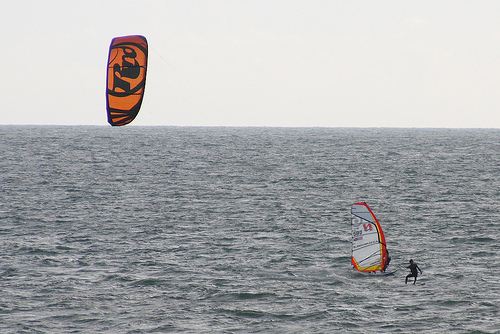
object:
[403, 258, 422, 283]
person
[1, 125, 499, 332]
water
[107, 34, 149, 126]
parasail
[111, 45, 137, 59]
lettering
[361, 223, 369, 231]
numbers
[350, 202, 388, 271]
parasail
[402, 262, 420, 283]
wetsuit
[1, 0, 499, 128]
sky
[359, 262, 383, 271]
strip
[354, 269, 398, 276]
board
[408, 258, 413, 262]
head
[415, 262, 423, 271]
arm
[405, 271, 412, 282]
leg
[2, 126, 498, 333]
some ripples